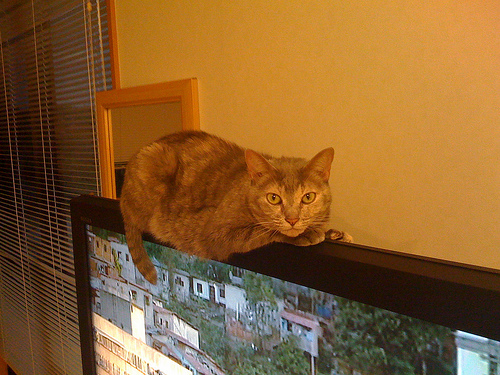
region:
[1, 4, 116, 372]
white blinds are covering the window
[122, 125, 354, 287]
the cat is gray and white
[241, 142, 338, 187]
the cat has two ears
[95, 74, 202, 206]
a mirror is hanging on the wall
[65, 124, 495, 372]
a cat is sitting on top of the television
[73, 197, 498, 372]
the television is on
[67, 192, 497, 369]
the frame of the television is black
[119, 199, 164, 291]
the tail of the cat is striped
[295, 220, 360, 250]
two cat paws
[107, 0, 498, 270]
the wall is painted yellow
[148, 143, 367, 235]
the cat is staring at someone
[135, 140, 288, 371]
cat laying on tv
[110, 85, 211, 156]
picture frame near the cat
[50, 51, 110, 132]
windows are closed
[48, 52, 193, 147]
the window near the picture frame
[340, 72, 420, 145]
no wallpaper on the wall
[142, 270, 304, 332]
TV is turn on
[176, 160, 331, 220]
cat is not in good mood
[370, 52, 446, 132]
wall is white colors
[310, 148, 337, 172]
the cat is awake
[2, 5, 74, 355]
blinds on the window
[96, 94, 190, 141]
a mirror on the wall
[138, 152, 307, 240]
cat on the television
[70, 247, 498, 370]
the television the cat is sitting on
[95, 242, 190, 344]
gray houses on the television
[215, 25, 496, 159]
the yellow wall of the house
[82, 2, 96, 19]
the handle of the blinds pull string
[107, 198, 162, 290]
the cats tail over the television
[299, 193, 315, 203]
the eye of the cat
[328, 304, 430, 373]
a tree on the television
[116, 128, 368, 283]
orange cat perched on ledge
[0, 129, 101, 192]
venetian blinds on window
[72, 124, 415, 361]
orange striped cat lying on top of flat screen tv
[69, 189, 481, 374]
big screen television against yellow wall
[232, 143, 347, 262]
smiling cat with golden eyes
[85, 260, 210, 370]
old white buildings crowded together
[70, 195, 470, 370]
big screen tv showing television show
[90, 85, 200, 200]
mirror hanging on wall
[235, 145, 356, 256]
cat resting chin on paw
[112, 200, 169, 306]
cat's tail hanging down on tv screen